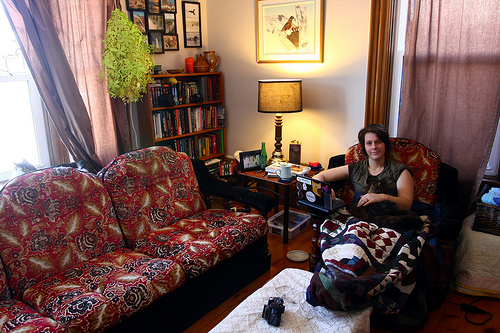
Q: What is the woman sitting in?
A: A chair.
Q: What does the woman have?
A: Blanket.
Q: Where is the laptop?
A: With woman in chair.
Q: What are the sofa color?
A: Red and black formal sofa.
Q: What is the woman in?
A: A chair.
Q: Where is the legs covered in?
A: Legs covered with quito.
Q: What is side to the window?
A: Tree.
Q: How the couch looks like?
A: Good.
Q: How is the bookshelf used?
A: Books.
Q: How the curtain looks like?
A: Brown.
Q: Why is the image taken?
A: To show others.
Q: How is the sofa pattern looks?
A: Crazy pattern.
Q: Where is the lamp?
A: End table by Chair.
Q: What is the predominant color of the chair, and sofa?
A: Red.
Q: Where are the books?
A: Bookcase.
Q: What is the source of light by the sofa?
A: Window.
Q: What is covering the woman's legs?
A: Quilt.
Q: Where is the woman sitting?
A: Chair.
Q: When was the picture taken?
A: Daytime.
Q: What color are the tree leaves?
A: Green.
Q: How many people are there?
A: One.